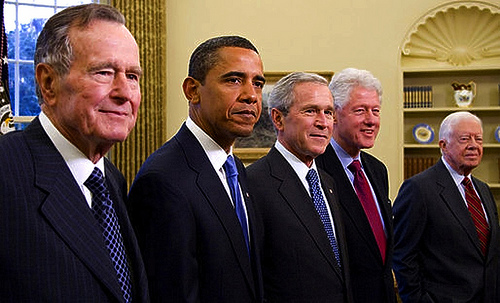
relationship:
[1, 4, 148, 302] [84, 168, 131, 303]
george bush wears tie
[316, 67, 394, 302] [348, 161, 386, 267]
bill clinton wears tie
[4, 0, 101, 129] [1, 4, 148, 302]
window behind george bush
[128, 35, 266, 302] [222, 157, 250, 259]
barack obama has tie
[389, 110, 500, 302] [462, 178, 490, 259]
jimmy carter has tie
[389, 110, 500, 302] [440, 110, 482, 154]
jimmy carter has hair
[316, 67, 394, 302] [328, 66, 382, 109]
bill clinton has hair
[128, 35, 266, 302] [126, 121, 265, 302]
barack obama wears suit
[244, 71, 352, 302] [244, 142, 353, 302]
george bush wears suit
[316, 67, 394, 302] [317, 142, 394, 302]
bill clinton wears suit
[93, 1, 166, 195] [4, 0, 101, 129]
drapes on window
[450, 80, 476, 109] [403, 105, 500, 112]
pitcher on shelf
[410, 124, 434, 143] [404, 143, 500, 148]
plate on shelf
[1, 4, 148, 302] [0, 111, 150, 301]
george bush wears suit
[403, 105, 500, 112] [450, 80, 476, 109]
shelf with pitcher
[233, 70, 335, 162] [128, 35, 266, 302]
painting behind barack obama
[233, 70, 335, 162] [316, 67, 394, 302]
painting behind bill clinton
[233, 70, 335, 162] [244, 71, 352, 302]
painting behind george bush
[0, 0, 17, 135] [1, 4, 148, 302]
flag behind george bush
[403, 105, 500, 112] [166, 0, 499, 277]
shelf set into wall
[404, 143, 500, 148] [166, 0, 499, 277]
shelf set into wall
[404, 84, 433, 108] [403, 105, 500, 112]
books on shelf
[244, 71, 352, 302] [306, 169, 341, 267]
george bush wears tie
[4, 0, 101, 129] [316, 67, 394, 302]
window behind bill clinton